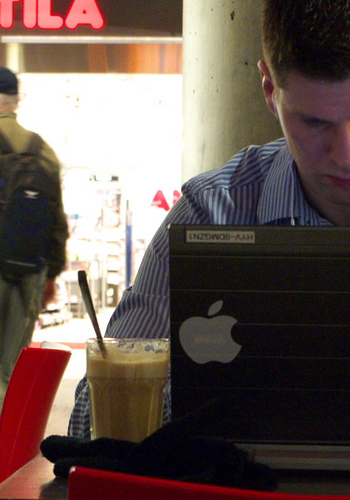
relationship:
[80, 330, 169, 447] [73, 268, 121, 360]
glass has spoon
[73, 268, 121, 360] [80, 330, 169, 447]
spoon in glass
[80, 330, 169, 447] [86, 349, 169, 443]
glass has coffee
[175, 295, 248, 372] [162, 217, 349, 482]
apple logo on laptop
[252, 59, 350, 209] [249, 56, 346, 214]
half of face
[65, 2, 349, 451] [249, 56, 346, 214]
person has face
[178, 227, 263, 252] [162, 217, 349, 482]
label on laptop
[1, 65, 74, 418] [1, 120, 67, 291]
person wearing backpack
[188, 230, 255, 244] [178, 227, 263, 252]
serial number on label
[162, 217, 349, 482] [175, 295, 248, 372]
laptop has apple logo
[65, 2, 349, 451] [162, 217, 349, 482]
person using laptop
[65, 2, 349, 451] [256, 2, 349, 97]
person has hair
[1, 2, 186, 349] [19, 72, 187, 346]
store has entrance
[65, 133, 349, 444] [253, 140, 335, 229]
shirt has collar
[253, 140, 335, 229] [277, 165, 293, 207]
collar has stripes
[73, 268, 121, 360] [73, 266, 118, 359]
spoon has handle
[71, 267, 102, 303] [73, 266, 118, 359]
part of handle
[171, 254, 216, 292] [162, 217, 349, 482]
part of laptop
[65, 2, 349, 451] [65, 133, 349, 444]
person has shirt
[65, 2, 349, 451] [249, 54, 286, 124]
person has ear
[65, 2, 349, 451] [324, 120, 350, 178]
person has nose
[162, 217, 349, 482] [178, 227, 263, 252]
laptop has label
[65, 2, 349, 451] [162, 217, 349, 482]
person looking at laptop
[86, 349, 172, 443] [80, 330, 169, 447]
coffee in glass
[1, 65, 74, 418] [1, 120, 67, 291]
person has backpack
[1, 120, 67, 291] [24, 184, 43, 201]
backpack has lettering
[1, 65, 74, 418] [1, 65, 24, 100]
person wearing cap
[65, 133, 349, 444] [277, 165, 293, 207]
shirt has stripes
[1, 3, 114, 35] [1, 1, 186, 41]
letters are on sign